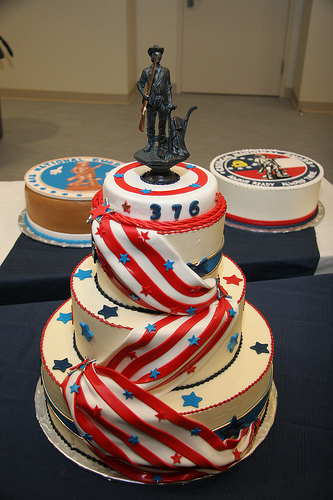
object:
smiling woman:
[65, 160, 104, 191]